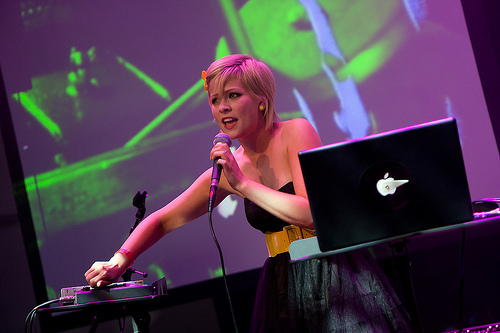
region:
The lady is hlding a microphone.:
[194, 116, 315, 210]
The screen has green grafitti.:
[35, 56, 191, 216]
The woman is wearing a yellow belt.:
[245, 218, 324, 260]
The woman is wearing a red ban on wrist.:
[118, 245, 145, 263]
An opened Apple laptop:
[292, 118, 480, 250]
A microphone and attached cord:
[198, 130, 240, 318]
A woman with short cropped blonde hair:
[197, 55, 277, 147]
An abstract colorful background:
[288, 7, 449, 108]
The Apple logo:
[371, 173, 413, 198]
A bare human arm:
[242, 174, 307, 224]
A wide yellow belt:
[258, 218, 330, 267]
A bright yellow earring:
[256, 98, 264, 116]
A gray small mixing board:
[52, 273, 172, 306]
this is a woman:
[68, 36, 362, 328]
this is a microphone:
[174, 105, 252, 312]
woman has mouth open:
[216, 109, 241, 137]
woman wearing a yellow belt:
[246, 212, 313, 274]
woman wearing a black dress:
[217, 154, 311, 330]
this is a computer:
[246, 72, 484, 263]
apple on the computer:
[368, 160, 420, 197]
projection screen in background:
[14, 0, 486, 303]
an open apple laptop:
[274, 102, 483, 247]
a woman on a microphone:
[55, 38, 448, 327]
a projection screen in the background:
[5, 8, 491, 324]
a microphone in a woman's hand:
[190, 131, 237, 225]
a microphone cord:
[194, 198, 260, 324]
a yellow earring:
[255, 101, 267, 112]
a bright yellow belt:
[242, 213, 339, 261]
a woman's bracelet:
[109, 238, 150, 270]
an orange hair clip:
[186, 53, 213, 95]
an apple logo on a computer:
[366, 164, 413, 209]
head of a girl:
[185, 49, 292, 146]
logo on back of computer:
[345, 153, 416, 223]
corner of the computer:
[406, 93, 480, 167]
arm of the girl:
[86, 157, 233, 281]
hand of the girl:
[67, 238, 130, 298]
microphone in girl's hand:
[176, 117, 245, 209]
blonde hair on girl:
[200, 41, 290, 118]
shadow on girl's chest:
[233, 147, 292, 189]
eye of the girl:
[214, 78, 246, 115]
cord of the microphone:
[192, 223, 249, 332]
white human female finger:
[214, 155, 230, 170]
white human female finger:
[205, 140, 230, 153]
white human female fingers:
[206, 142, 233, 174]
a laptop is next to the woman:
[300, 113, 470, 255]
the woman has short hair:
[200, 57, 289, 145]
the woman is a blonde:
[207, 58, 284, 147]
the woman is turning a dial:
[76, 247, 131, 300]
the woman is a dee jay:
[80, 58, 347, 310]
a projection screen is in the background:
[2, 4, 494, 301]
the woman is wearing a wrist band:
[116, 246, 134, 266]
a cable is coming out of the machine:
[22, 273, 75, 330]